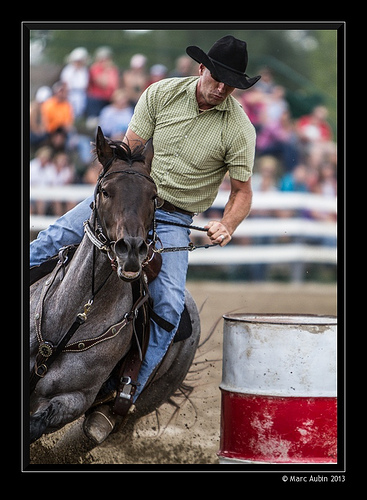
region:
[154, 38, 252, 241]
this is a man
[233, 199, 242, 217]
the man has a light skin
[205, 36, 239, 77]
this is a hat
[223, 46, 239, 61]
the hat is black in color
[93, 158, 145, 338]
this is a horse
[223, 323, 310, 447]
this is a drum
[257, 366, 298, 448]
the drum is red and white in color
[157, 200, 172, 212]
this is a belt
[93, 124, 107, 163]
this is a ear of the horse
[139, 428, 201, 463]
this is the ground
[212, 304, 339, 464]
red and white barrel in lower right corner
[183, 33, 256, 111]
black cowboy hat on head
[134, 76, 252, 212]
green and black checked shirt on cowboy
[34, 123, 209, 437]
brown horse racing around barrel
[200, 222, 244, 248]
ring on cowboys's hand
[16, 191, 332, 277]
three white rails on fence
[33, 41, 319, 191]
spectators in the stands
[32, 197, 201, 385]
blue jeans cowboy is wearing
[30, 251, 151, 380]
conchos on horse's harness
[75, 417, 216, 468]
dirt being kicked up by horse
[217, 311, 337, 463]
white and red barrel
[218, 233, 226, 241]
ring on man's finger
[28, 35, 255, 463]
man riding a horse at a rodeo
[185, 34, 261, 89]
black hat on cowboy's head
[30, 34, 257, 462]
cowboy riding a brown and gray horse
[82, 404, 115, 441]
toe of cowboy's boot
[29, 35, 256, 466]
horse running fast with cowboy on the back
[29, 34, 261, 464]
cowboy wearing a black hat leaning on the horse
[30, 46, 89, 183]
patrons watching the rodeo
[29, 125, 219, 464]
horse running around a red and white barrel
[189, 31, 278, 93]
Man wearing black hat.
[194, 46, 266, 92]
Black hat is cowboy hat.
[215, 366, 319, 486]
Red and white barrel near horse.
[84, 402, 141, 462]
Man wearing dark boots.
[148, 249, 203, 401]
Man wearing blue jeans.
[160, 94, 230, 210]
Man wearing green button down shirt.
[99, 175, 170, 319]
Black straps on horse's face.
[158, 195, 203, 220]
Man wearing brown belt.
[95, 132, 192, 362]
Man riding horse in arena.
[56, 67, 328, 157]
People watching cowboy in stands.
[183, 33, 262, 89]
The black hat the rider is wearing.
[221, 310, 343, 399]
Top white part of the pin.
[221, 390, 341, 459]
The red part of the bin.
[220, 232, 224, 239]
The ring on the rider's finger.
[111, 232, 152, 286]
The horse's mouth and nose.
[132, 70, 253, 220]
The plaid shirt the rider is wearing.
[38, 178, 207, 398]
The blue jeans the rider is wearing.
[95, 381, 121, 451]
The boot the rider is wearing.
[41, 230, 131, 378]
The harness around the horse's neck.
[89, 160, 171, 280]
The harness around the horse's head.